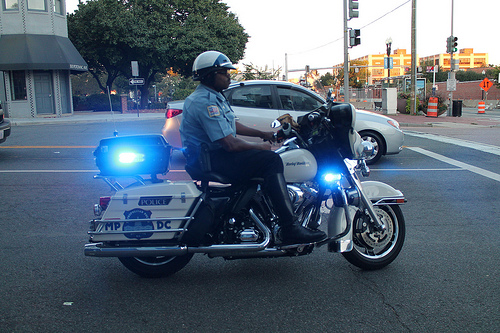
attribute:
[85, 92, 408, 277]
motorcycle — white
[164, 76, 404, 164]
car — sedan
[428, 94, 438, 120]
barrel — orange, white, reflective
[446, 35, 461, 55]
trafficlight — green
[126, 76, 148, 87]
one way — black, white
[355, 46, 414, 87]
building — brick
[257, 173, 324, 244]
boot — black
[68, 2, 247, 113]
trees — green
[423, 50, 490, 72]
large building — distant